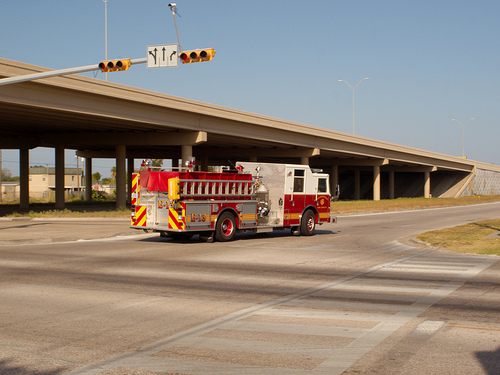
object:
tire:
[215, 211, 236, 242]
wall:
[452, 166, 500, 205]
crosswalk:
[65, 251, 499, 374]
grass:
[414, 218, 500, 258]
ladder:
[167, 177, 256, 201]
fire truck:
[128, 157, 341, 243]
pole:
[0, 42, 216, 87]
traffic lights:
[97, 58, 131, 73]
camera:
[165, 2, 185, 47]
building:
[0, 166, 118, 205]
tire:
[301, 208, 315, 237]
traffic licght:
[179, 47, 216, 64]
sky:
[0, 0, 499, 175]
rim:
[220, 218, 234, 237]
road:
[0, 196, 499, 374]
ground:
[0, 199, 499, 374]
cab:
[234, 161, 341, 236]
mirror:
[335, 184, 341, 199]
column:
[19, 148, 29, 212]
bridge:
[0, 53, 499, 212]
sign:
[144, 45, 178, 68]